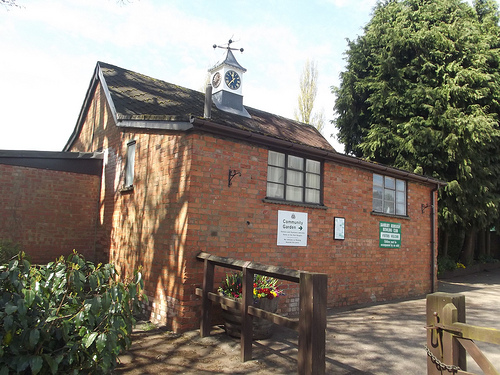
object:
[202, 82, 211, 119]
chimney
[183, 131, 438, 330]
wall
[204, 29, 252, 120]
clock tower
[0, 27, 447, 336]
brick building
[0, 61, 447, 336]
brick house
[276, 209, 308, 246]
signs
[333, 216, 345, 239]
signs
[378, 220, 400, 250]
signs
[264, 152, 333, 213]
window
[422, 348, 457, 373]
chain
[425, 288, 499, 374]
gate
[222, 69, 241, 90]
clock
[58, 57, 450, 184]
roof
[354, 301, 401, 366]
dirt.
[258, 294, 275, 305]
vase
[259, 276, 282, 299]
flowers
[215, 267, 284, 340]
box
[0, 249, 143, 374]
shrub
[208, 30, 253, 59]
vane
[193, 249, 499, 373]
fence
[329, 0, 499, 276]
tree